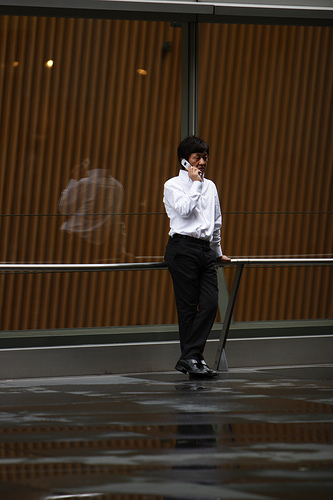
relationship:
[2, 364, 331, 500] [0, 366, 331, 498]
water on road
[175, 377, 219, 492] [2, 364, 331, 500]
reflection in water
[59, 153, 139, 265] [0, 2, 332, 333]
reflection in window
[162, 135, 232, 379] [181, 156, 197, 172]
man on phone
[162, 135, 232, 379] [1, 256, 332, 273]
man on rail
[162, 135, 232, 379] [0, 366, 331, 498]
man on road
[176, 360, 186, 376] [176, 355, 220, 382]
heel on shoes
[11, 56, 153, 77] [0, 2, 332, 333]
reflection in window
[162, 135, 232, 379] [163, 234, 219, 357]
man wearing pants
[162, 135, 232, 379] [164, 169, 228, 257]
man wearing shirt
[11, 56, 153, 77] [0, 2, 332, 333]
reflection on window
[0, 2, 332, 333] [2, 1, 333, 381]
window on building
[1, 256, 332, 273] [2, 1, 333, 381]
rail at building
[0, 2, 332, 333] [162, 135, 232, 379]
window behind man